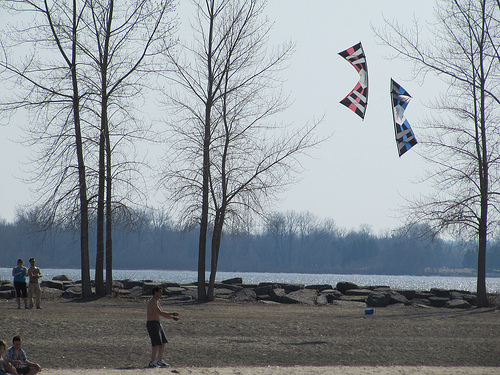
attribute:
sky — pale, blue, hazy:
[3, 2, 499, 241]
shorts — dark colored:
[145, 322, 168, 346]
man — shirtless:
[123, 275, 195, 353]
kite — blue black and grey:
[385, 75, 423, 165]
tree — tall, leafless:
[0, 1, 182, 296]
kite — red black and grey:
[335, 38, 370, 119]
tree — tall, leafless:
[152, 0, 333, 302]